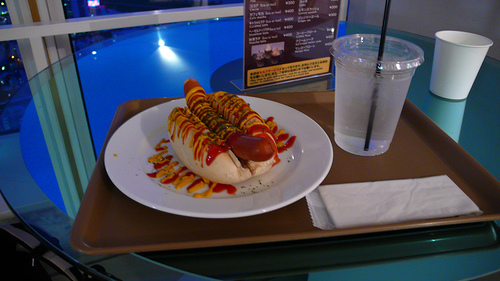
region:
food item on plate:
[163, 73, 288, 170]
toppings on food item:
[168, 63, 272, 173]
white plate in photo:
[97, 140, 140, 199]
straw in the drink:
[366, 4, 418, 34]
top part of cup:
[318, 24, 433, 90]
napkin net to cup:
[344, 155, 439, 219]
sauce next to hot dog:
[148, 162, 193, 192]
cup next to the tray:
[431, 27, 486, 110]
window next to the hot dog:
[101, 10, 207, 80]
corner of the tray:
[55, 212, 130, 276]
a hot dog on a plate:
[106, 78, 356, 231]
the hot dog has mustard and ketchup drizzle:
[152, 78, 298, 208]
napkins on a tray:
[294, 170, 494, 232]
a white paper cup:
[426, 9, 493, 116]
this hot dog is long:
[176, 79, 278, 171]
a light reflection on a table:
[132, 22, 214, 84]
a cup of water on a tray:
[327, 10, 454, 167]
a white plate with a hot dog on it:
[115, 63, 332, 222]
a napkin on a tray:
[306, 150, 476, 243]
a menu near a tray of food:
[223, 0, 355, 102]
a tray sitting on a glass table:
[62, 0, 459, 272]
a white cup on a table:
[416, 3, 496, 115]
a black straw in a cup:
[360, 0, 405, 149]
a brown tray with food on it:
[61, 51, 484, 255]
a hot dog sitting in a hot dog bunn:
[171, 62, 293, 186]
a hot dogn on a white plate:
[145, 75, 298, 187]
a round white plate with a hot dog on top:
[98, 84, 312, 213]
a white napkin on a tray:
[301, 162, 465, 242]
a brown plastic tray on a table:
[69, 221, 281, 257]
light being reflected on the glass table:
[146, 30, 189, 70]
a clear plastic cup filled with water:
[331, 18, 417, 160]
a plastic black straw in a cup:
[358, 0, 401, 152]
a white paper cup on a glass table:
[423, 23, 486, 110]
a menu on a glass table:
[237, 0, 336, 87]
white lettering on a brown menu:
[250, 9, 314, 41]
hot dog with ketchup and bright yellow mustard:
[166, 78, 280, 185]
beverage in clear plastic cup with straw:
[333, 1, 423, 156]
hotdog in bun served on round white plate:
[103, 78, 332, 217]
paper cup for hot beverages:
[430, 29, 492, 100]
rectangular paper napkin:
[304, 173, 481, 227]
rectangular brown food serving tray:
[71, 89, 498, 253]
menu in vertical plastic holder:
[231, 0, 339, 89]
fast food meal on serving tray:
[75, 0, 497, 260]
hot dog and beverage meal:
[63, 0, 421, 220]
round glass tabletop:
[15, 16, 496, 278]